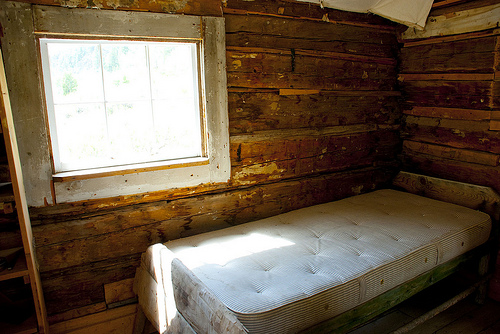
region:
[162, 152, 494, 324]
a twin bed mattress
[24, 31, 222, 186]
a window with no blinds or curtains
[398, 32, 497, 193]
the wall of a log cabin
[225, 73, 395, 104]
logs with some mortar missing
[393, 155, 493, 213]
small headboard on a twin board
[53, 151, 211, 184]
a sill below the window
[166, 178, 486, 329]
a mattress with no bedding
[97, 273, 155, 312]
a white board near the floor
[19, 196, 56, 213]
paint peeling from the window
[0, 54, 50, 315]
a board standing near a wall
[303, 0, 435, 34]
insulation about to fall from the ceiling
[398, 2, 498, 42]
white mismatched board used a wall no doubt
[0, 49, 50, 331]
build in light wooden shelf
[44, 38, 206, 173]
really old and dirty window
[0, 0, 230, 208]
'white' trim going around the window for accent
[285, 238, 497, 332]
green box spring or regular mattress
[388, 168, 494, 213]
wannabe headboard made out of wood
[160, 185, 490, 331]
dirty white mattress with thin, faint, light blue stripes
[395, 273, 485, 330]
metal pole near the floor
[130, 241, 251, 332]
something covered in dirty cloth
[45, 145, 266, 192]
The flat window ledge.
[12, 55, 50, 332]
Part of the bookshelf that is visible.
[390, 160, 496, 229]
The headboard of the bed.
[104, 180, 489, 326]
The white button mattress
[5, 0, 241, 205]
The window encased by white wood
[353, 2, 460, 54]
The area of the ceiling that appears to be falling down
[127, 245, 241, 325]
The foot board of the bed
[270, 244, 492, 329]
The green board underneath the mattress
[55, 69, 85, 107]
The green tree visible outside through the window.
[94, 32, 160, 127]
The top center section of the window.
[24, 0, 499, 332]
a rustic log cabin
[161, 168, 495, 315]
a single cot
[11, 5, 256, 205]
the window frame is white/grey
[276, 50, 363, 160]
the logs appear very old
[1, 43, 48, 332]
it appears there is a shelf in the corner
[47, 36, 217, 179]
the window is divided into 6 panes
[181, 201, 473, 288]
the mattress has buttons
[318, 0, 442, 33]
something is hanging down from the ceiling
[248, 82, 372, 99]
the logs are missing alot of chinking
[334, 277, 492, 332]
the bottom of the bed is green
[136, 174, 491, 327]
several mattress stacked in corner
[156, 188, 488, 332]
white mattress on top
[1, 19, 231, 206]
white paint on window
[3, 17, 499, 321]
log timber walls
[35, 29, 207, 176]
window is square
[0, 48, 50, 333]
wood shelves agains wall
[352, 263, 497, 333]
metal roll frame under mattress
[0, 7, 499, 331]
timber walls are brown and tan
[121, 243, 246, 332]
footboard is white and wooden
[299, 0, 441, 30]
white material hanging from ceiling